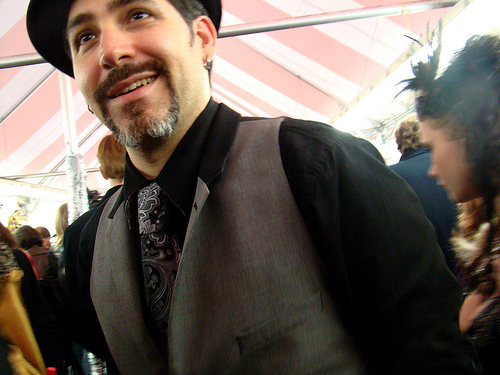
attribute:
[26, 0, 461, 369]
man — standing, light skinned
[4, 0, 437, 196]
tent — striped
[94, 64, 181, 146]
goatee — gray, black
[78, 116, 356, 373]
vest — gray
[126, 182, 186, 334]
tie — gray, black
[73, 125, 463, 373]
shirt — black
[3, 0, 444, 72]
pole — silver, metal, verticle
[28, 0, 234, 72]
hat — black